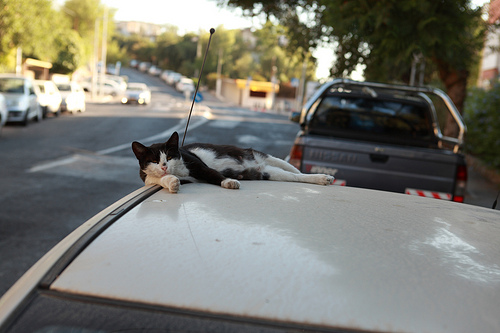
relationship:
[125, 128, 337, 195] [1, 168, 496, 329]
cat on hood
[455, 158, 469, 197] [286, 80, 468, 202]
brake light on car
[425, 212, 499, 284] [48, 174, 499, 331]
reflection on roof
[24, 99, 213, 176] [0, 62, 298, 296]
line on road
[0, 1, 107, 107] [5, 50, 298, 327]
trees on road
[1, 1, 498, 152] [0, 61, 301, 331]
trees near street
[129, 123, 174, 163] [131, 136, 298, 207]
head on cat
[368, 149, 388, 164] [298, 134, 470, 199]
handle on truck back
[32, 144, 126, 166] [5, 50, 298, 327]
line on road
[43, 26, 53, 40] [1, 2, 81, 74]
leaves on tree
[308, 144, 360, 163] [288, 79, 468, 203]
word on truck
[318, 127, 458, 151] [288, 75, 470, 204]
bed on pickup truck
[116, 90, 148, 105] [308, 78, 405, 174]
headlights on car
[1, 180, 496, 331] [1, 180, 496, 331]
car roof on car roof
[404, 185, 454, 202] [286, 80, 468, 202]
stripes on car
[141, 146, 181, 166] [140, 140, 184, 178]
black spot on cat's face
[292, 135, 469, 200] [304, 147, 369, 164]
back says nissan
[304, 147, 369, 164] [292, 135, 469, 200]
nissan on back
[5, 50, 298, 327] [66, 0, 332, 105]
road on hill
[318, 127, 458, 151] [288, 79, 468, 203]
bed on truck